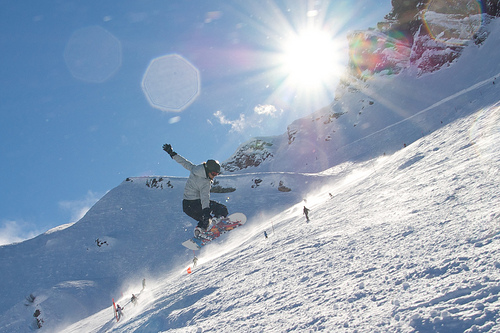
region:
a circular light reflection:
[111, 50, 237, 130]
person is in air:
[161, 159, 243, 265]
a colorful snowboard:
[181, 205, 247, 267]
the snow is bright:
[261, 211, 451, 326]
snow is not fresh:
[274, 207, 434, 302]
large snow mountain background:
[41, 169, 158, 296]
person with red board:
[95, 290, 137, 322]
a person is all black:
[273, 205, 335, 237]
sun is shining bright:
[257, 14, 368, 100]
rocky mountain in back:
[343, 12, 490, 107]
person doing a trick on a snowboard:
[152, 141, 255, 246]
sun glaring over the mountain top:
[267, 22, 351, 99]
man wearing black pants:
[173, 189, 233, 229]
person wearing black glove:
[152, 141, 177, 163]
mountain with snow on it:
[91, 167, 178, 257]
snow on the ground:
[408, 189, 488, 319]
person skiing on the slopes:
[300, 207, 314, 221]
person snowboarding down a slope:
[163, 140, 250, 256]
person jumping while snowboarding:
[156, 135, 248, 257]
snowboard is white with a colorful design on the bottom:
[183, 207, 248, 254]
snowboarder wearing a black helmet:
[205, 160, 222, 180]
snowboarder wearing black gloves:
[160, 142, 217, 229]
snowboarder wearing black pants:
[178, 192, 228, 234]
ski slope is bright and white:
[3, 0, 499, 330]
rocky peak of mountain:
[325, 0, 497, 103]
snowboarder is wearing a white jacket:
[169, 147, 224, 213]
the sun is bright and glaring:
[268, 22, 342, 97]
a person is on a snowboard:
[159, 134, 255, 254]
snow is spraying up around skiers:
[106, 264, 158, 321]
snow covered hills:
[0, 165, 336, 328]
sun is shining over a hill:
[238, 15, 369, 126]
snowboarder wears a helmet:
[157, 141, 250, 260]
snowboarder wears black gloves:
[159, 140, 246, 252]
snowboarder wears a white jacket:
[159, 140, 248, 250]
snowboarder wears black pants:
[158, 139, 250, 254]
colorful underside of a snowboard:
[179, 208, 248, 255]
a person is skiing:
[301, 203, 315, 225]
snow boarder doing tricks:
[167, 129, 239, 223]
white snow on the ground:
[41, 36, 68, 68]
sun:
[247, 12, 347, 102]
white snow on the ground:
[30, 121, 51, 139]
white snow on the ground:
[48, 43, 85, 87]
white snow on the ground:
[11, 122, 43, 154]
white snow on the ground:
[180, 51, 221, 129]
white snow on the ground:
[47, 46, 128, 106]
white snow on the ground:
[20, 148, 105, 210]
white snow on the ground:
[70, 56, 118, 96]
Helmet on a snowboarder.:
[206, 157, 223, 177]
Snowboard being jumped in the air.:
[167, 210, 251, 252]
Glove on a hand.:
[161, 141, 173, 156]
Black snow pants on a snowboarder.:
[180, 198, 232, 233]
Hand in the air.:
[156, 129, 181, 161]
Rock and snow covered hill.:
[231, 95, 448, 232]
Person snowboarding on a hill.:
[103, 292, 126, 319]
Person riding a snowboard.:
[296, 205, 316, 222]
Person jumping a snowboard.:
[156, 125, 285, 277]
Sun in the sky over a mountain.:
[228, 7, 355, 129]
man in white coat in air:
[154, 133, 255, 257]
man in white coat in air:
[146, 128, 250, 263]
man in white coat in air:
[158, 138, 254, 263]